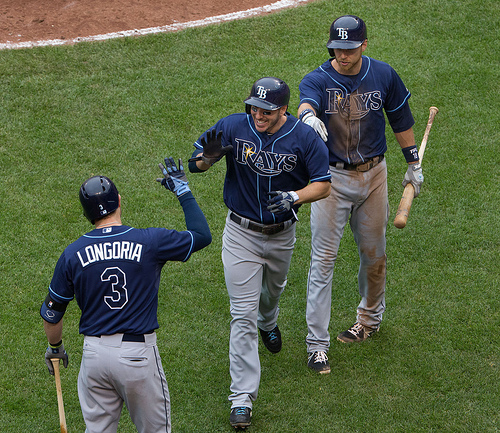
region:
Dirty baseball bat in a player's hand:
[390, 89, 442, 245]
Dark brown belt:
[215, 200, 307, 243]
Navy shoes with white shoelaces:
[302, 322, 377, 376]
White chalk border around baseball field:
[1, 2, 286, 59]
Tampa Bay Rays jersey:
[215, 132, 322, 218]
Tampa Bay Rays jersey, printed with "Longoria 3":
[43, 230, 189, 350]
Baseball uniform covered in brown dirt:
[315, 79, 405, 331]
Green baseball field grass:
[403, 255, 489, 431]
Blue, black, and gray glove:
[149, 155, 199, 200]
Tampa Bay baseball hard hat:
[240, 72, 290, 114]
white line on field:
[39, 15, 135, 50]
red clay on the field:
[27, 4, 104, 26]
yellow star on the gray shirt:
[237, 144, 278, 167]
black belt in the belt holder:
[222, 205, 319, 235]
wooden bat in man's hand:
[397, 93, 428, 257]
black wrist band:
[378, 133, 444, 183]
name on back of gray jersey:
[49, 230, 214, 298]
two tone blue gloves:
[140, 148, 199, 208]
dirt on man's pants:
[350, 229, 410, 329]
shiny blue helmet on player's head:
[223, 59, 315, 141]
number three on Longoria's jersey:
[76, 236, 148, 313]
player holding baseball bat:
[388, 93, 444, 237]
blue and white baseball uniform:
[186, 74, 326, 427]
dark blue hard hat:
[320, 14, 369, 51]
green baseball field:
[0, 1, 497, 429]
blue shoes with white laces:
[304, 345, 337, 379]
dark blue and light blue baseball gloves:
[153, 157, 195, 198]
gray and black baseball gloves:
[401, 143, 426, 192]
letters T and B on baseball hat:
[334, 25, 353, 44]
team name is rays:
[229, 133, 302, 181]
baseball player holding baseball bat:
[33, 156, 200, 423]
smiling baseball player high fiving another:
[180, 65, 321, 404]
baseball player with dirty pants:
[301, 29, 420, 359]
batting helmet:
[66, 162, 131, 227]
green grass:
[37, 75, 148, 150]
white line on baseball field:
[45, 20, 170, 70]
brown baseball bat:
[389, 76, 453, 258]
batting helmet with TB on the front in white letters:
[245, 75, 297, 125]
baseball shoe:
[303, 338, 338, 386]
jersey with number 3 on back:
[52, 215, 178, 330]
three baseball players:
[36, 17, 424, 422]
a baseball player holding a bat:
[298, 13, 440, 373]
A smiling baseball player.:
[187, 75, 332, 420]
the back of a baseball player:
[46, 154, 212, 431]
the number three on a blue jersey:
[51, 220, 194, 332]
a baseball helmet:
[245, 76, 291, 116]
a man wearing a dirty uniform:
[299, 16, 411, 341]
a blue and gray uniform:
[198, 112, 328, 405]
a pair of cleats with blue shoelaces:
[227, 326, 284, 430]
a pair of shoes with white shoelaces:
[306, 321, 383, 373]